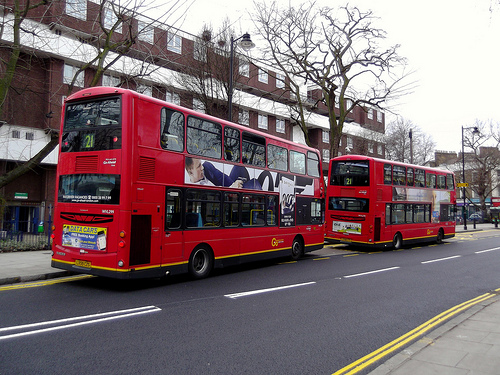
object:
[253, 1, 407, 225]
trees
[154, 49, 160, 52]
brick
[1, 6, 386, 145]
trim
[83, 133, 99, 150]
number 21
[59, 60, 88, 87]
window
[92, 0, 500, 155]
sky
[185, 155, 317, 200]
advertisement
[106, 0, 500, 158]
clouds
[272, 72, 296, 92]
window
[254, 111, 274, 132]
window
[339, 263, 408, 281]
line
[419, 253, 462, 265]
line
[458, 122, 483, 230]
light post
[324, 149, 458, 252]
bus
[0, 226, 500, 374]
lane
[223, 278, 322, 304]
dividers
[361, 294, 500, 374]
sidewalk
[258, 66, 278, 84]
window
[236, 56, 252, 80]
window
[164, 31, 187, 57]
window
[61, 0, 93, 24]
window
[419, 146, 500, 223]
building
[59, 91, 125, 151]
window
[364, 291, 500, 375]
curb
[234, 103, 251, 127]
window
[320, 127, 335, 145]
window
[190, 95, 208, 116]
window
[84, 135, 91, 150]
number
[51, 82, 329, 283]
bus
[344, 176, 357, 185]
21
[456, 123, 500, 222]
tree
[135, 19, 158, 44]
window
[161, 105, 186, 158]
windows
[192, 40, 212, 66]
window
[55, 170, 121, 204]
window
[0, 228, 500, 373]
street